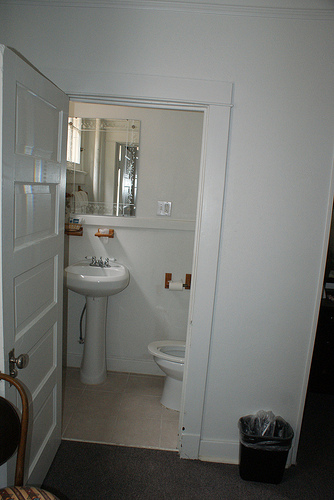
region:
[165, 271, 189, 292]
Toilet paper holder in bathroom.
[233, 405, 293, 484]
Garbage can against the wall.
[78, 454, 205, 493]
Carpet on the floor.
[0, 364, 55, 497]
Chair beside the door.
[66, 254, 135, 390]
White sink in bathroom.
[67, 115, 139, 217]
Mirror in the bathroom.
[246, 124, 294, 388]
White paint on the wall.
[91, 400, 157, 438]
Tile floor on the bathroom.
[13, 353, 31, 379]
Door knob on the door.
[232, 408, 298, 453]
A clear garbage can liner.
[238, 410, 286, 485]
garbage can on the floor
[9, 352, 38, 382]
knob on the door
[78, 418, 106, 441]
tile on the floor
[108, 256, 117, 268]
knob on the sink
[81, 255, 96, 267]
knob on the sink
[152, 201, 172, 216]
outlet on the wall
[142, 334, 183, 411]
toilet on the floor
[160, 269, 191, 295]
toilet paper holder on wall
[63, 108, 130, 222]
mirror on the wall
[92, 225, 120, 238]
toothbrush holder on wall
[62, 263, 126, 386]
porcelain sink on a stand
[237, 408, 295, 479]
waste basket with a plastic liner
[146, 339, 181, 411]
toilet with the lid up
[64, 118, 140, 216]
a mirror in the bathroom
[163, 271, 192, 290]
a toilet paper roll on a rack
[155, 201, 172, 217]
electrical outlet and light switch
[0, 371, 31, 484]
rounded back on a wooden chair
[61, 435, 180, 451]
the strip between carpet and tile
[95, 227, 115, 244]
cups hanging on the wall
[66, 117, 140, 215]
reflection in the mirror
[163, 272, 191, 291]
brown wooden toilet dispenser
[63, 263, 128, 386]
white pedestal bathroom sink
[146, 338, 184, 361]
white plastic toilet seat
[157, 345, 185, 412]
white ceramic toilet bowl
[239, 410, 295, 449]
clear plastic garbage bag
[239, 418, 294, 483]
black garbage can with plastic bag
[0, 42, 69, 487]
wooden door is white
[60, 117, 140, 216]
bathroom mirror with decorative edging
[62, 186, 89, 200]
wooden towel rack is hanging on wall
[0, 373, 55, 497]
chair with wooden back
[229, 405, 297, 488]
A trash can in the foreground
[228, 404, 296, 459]
Trash can has a trash bag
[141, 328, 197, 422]
A toilet is in view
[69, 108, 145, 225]
A Mirror is in the background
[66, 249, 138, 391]
A bathroom sink in the background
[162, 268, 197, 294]
A toilet roll in the background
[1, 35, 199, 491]
Bathroom door is open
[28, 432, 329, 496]
Carpet is on the floor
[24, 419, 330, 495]
The carpet is gray in color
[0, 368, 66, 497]
A chair in the foreground